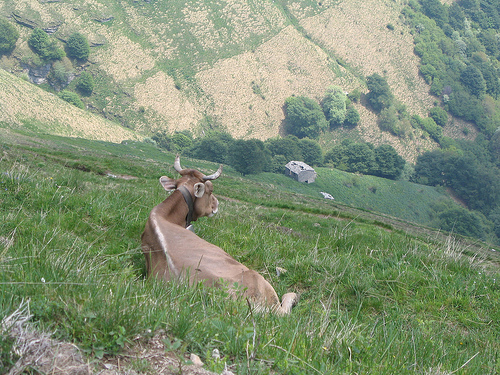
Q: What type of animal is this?
A: A cow.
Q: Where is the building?
A: Down below.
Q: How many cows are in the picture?
A: 1.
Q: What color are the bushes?
A: Green.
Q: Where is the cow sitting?
A: On a hill.